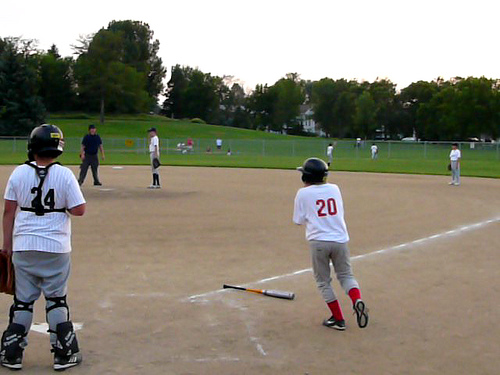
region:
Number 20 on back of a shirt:
[311, 194, 341, 223]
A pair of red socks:
[323, 283, 363, 319]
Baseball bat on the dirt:
[213, 273, 299, 313]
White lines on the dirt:
[94, 217, 498, 363]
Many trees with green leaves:
[1, 17, 499, 141]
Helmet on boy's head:
[23, 118, 66, 163]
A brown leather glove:
[1, 243, 21, 296]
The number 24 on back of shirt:
[24, 178, 60, 218]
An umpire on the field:
[73, 122, 109, 192]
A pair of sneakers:
[321, 295, 374, 335]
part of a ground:
[187, 238, 222, 286]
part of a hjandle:
[228, 265, 263, 317]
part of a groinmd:
[161, 283, 200, 343]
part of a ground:
[186, 289, 220, 329]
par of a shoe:
[348, 305, 363, 361]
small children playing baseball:
[17, 98, 496, 272]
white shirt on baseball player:
[279, 182, 389, 251]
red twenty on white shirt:
[302, 195, 350, 225]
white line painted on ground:
[351, 179, 481, 285]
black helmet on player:
[287, 162, 334, 187]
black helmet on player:
[29, 115, 81, 155]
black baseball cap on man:
[144, 129, 163, 143]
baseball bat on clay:
[226, 276, 296, 313]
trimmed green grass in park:
[19, 112, 421, 178]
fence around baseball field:
[55, 126, 490, 213]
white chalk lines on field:
[212, 302, 269, 353]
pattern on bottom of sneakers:
[348, 295, 373, 332]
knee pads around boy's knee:
[10, 287, 87, 337]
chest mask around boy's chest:
[7, 159, 85, 219]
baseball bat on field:
[208, 273, 303, 310]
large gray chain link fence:
[327, 131, 477, 162]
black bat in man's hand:
[145, 151, 177, 179]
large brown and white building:
[291, 98, 332, 140]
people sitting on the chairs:
[173, 134, 202, 160]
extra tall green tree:
[64, 15, 184, 119]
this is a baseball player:
[287, 151, 369, 303]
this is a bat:
[220, 275, 295, 308]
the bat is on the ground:
[223, 278, 296, 308]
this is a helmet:
[303, 160, 326, 180]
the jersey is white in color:
[302, 189, 338, 230]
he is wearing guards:
[50, 305, 77, 372]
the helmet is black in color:
[305, 158, 327, 179]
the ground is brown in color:
[155, 185, 239, 267]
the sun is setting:
[311, 25, 382, 63]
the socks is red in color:
[328, 301, 341, 313]